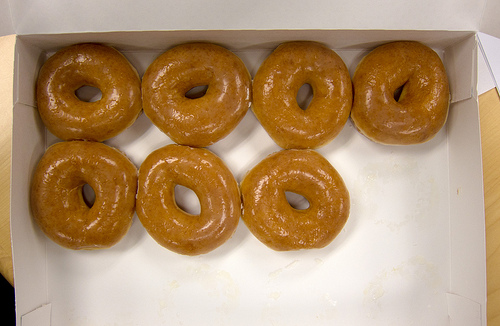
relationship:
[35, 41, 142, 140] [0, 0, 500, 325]
doughnut in box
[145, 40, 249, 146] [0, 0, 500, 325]
doughnut in box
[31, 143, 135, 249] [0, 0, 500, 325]
doughnut in box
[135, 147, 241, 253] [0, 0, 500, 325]
doughnut in box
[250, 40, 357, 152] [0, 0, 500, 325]
doughnut in box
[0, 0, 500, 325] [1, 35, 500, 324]
box on table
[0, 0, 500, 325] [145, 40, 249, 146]
box filled with doughnut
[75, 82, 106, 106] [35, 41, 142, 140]
hole in doughnut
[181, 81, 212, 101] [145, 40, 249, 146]
hole in doughnut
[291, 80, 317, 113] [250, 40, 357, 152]
hole in doughnut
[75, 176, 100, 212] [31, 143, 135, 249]
hole in doughnut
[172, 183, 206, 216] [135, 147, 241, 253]
hole in doughnut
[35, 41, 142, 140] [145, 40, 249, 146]
doughnut next to doughnut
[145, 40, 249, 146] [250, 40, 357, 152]
doughnut next to doughnut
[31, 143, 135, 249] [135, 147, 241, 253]
doughnut next to doughnut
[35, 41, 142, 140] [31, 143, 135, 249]
doughnut next to doughnut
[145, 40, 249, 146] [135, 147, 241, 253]
doughnut next to doughnut